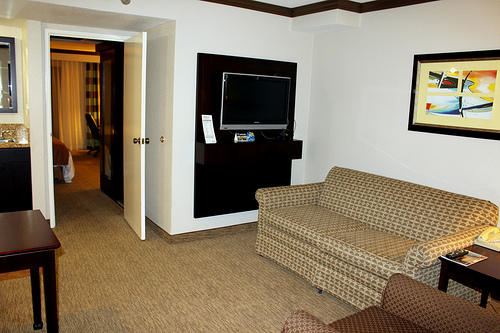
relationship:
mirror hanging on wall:
[0, 35, 20, 115] [0, 25, 22, 122]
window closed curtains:
[52, 55, 102, 158] [52, 57, 89, 156]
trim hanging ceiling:
[204, 0, 444, 18] [198, 0, 443, 23]